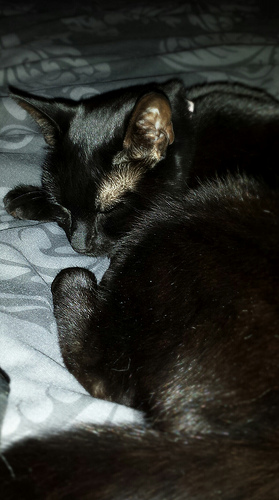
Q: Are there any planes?
A: No, there are no planes.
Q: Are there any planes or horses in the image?
A: No, there are no planes or horses.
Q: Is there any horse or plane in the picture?
A: No, there are no airplanes or horses.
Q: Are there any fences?
A: No, there are no fences.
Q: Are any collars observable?
A: Yes, there is a collar.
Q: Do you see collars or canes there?
A: Yes, there is a collar.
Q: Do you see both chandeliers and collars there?
A: No, there is a collar but no chandeliers.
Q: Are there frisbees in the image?
A: No, there are no frisbees.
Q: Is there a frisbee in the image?
A: No, there are no frisbees.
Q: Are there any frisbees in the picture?
A: No, there are no frisbees.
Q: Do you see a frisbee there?
A: No, there are no frisbees.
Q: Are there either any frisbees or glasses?
A: No, there are no frisbees or glasses.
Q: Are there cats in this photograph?
A: Yes, there is a cat.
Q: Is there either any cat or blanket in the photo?
A: Yes, there is a cat.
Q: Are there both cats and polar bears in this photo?
A: No, there is a cat but no polar bears.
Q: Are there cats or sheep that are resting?
A: Yes, the cat is resting.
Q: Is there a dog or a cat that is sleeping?
A: Yes, the cat is sleeping.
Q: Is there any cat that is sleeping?
A: Yes, there is a cat that is sleeping.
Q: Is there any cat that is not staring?
A: Yes, there is a cat that is sleeping.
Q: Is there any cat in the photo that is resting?
A: Yes, there is a cat that is resting.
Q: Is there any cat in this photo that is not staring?
A: Yes, there is a cat that is resting.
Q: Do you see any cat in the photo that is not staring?
A: Yes, there is a cat that is resting .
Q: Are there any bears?
A: No, there are no bears.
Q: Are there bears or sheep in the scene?
A: No, there are no bears or sheep.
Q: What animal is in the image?
A: The animal is a cat.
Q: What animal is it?
A: The animal is a cat.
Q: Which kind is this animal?
A: That is a cat.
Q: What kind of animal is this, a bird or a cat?
A: That is a cat.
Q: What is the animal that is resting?
A: The animal is a cat.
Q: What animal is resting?
A: The animal is a cat.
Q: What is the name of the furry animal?
A: The animal is a cat.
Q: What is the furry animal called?
A: The animal is a cat.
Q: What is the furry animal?
A: The animal is a cat.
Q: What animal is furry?
A: The animal is a cat.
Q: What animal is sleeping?
A: The animal is a cat.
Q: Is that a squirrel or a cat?
A: That is a cat.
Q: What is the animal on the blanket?
A: The animal is a cat.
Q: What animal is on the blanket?
A: The animal is a cat.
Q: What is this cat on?
A: The cat is on the blanket.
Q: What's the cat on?
A: The cat is on the blanket.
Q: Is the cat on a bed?
A: No, the cat is on a blanket.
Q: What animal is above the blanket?
A: The animal is a cat.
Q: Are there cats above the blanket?
A: Yes, there is a cat above the blanket.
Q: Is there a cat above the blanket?
A: Yes, there is a cat above the blanket.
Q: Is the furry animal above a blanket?
A: Yes, the cat is above a blanket.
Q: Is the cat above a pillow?
A: No, the cat is above a blanket.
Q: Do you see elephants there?
A: No, there are no elephants.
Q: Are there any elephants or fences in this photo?
A: No, there are no elephants or fences.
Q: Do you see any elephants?
A: No, there are no elephants.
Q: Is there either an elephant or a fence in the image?
A: No, there are no elephants or fences.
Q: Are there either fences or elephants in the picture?
A: No, there are no elephants or fences.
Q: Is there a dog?
A: No, there are no dogs.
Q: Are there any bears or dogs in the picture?
A: No, there are no dogs or bears.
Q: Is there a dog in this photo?
A: No, there are no dogs.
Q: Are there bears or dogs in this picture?
A: No, there are no dogs or bears.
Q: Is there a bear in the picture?
A: No, there are no bears.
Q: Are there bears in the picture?
A: No, there are no bears.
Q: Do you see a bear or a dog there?
A: No, there are no bears or dogs.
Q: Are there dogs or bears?
A: No, there are no bears or dogs.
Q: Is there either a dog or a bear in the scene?
A: No, there are no bears or dogs.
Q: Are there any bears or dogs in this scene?
A: No, there are no bears or dogs.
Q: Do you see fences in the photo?
A: No, there are no fences.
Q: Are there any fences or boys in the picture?
A: No, there are no fences or boys.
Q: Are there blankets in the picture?
A: Yes, there is a blanket.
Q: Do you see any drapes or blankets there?
A: Yes, there is a blanket.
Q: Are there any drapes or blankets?
A: Yes, there is a blanket.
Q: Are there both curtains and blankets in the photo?
A: No, there is a blanket but no curtains.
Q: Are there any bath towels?
A: No, there are no bath towels.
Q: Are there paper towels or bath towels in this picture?
A: No, there are no bath towels or paper towels.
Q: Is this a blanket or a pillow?
A: This is a blanket.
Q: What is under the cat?
A: The blanket is under the cat.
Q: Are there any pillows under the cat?
A: No, there is a blanket under the cat.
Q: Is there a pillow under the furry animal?
A: No, there is a blanket under the cat.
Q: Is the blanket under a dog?
A: No, the blanket is under a cat.